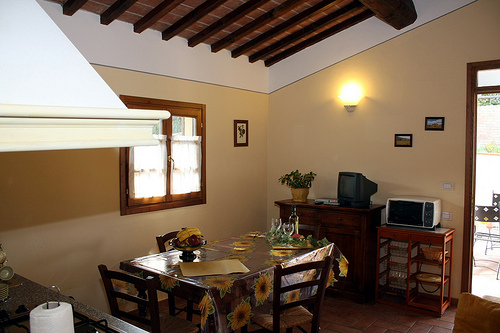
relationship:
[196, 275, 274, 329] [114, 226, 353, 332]
sunflowers on table cloth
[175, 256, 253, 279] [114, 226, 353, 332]
mat on table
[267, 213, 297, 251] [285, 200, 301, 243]
glasses of wine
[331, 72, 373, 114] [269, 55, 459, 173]
light on wall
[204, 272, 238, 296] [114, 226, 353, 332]
sunflower on table cloth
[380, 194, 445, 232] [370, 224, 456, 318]
oven on stand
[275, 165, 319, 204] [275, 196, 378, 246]
plant on stand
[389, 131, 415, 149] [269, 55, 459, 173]
picture on wall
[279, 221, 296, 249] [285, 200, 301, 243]
glass of wine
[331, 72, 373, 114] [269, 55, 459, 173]
light hanging on wall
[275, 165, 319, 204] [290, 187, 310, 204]
plant in tan pot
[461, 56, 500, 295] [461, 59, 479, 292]
door has wooden frame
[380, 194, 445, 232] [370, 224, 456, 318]
microwave on top of red stand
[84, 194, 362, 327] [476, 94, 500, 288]
dining area between kitchen and patio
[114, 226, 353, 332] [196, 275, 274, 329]
tablecloth covered with sunflowers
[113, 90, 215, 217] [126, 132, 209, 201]
window partially covered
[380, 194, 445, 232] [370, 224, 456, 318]
microwave on top of cart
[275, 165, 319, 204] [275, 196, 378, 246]
plant on storage cabinet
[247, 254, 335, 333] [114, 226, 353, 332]
chair under table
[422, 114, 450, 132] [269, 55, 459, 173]
picture on wall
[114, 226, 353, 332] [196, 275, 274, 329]
tablecloth has pictures